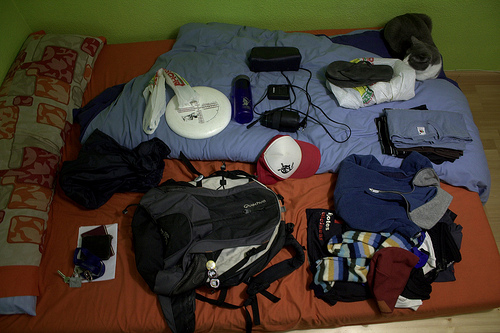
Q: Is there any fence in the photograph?
A: No, there are no fences.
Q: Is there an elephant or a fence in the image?
A: No, there are no fences or elephants.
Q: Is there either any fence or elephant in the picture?
A: No, there are no fences or elephants.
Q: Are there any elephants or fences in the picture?
A: No, there are no fences or elephants.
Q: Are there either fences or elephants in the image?
A: No, there are no fences or elephants.